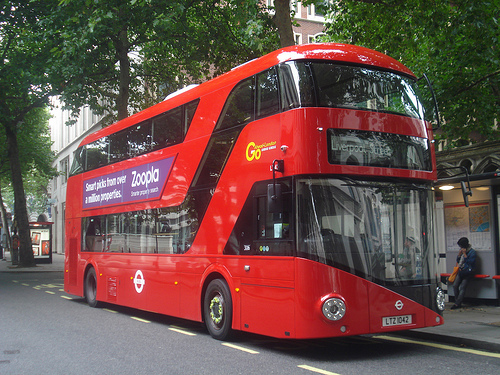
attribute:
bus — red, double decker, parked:
[64, 44, 448, 341]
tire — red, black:
[201, 277, 232, 340]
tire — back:
[84, 267, 97, 306]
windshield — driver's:
[295, 178, 436, 283]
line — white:
[298, 363, 339, 374]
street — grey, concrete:
[0, 270, 498, 374]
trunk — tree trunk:
[4, 126, 38, 266]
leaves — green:
[0, 0, 58, 119]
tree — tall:
[1, 0, 58, 269]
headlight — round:
[323, 298, 345, 321]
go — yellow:
[245, 141, 261, 162]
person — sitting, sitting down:
[450, 236, 485, 309]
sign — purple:
[82, 153, 178, 212]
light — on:
[436, 183, 453, 192]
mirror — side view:
[264, 181, 286, 239]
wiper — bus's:
[340, 179, 433, 193]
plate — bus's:
[382, 314, 414, 327]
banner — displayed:
[29, 228, 50, 257]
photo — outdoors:
[0, 1, 499, 373]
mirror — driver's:
[434, 187, 445, 288]